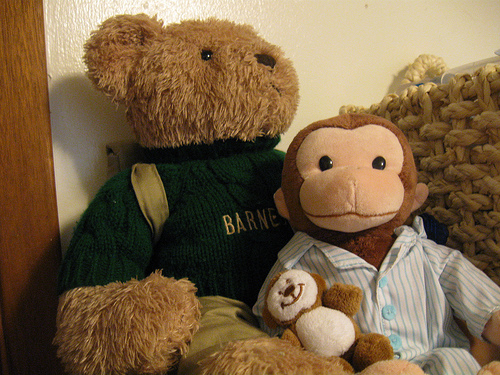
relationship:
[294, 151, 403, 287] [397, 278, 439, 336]
toy wearing pajamas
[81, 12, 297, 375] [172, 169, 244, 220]
toy wearing sweater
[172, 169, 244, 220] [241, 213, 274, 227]
sweater with embroidery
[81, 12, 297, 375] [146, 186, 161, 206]
toy wearing overalls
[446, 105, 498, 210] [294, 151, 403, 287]
basket behind toy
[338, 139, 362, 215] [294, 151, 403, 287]
face of toy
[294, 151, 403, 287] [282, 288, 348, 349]
toy holding teddy bear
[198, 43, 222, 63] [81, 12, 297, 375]
eye of toy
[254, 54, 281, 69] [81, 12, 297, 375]
nose of toy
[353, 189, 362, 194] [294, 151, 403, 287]
nose of toy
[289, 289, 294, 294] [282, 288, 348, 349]
nose of toy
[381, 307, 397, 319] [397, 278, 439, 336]
button on pajamas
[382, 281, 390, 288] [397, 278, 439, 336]
button on pajamas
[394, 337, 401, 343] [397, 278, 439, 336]
button on pajamas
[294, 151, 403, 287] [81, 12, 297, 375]
toy next to toy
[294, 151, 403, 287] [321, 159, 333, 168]
toy has eye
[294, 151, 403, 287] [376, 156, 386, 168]
toy has eye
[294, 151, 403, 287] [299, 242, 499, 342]
toy wearing pajamas